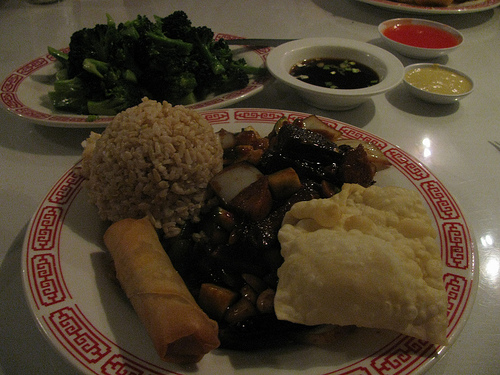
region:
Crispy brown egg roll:
[102, 210, 222, 367]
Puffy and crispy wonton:
[281, 176, 455, 347]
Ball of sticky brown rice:
[82, 97, 218, 230]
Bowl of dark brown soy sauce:
[268, 19, 412, 114]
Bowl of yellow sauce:
[402, 64, 479, 104]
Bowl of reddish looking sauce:
[376, 11, 464, 61]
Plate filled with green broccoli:
[5, 11, 274, 119]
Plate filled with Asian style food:
[28, 108, 473, 370]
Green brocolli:
[47, 24, 247, 88]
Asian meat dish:
[220, 116, 367, 193]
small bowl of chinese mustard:
[403, 58, 475, 110]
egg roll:
[95, 211, 220, 368]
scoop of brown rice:
[76, 101, 227, 233]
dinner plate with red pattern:
[19, 137, 140, 374]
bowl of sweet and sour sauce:
[367, 10, 466, 61]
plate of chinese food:
[20, 104, 475, 374]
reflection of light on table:
[396, 118, 456, 174]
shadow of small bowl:
[390, 73, 467, 120]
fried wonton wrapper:
[272, 164, 454, 354]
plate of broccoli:
[15, 21, 268, 110]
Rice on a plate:
[68, 114, 256, 224]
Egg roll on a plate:
[86, 223, 226, 352]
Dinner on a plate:
[89, 121, 471, 367]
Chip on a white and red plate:
[277, 195, 484, 345]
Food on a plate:
[135, 166, 300, 337]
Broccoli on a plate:
[51, 20, 274, 120]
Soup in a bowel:
[280, 37, 372, 117]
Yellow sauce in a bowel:
[405, 67, 460, 89]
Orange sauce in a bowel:
[373, 12, 439, 48]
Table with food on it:
[23, 17, 488, 286]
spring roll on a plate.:
[96, 212, 229, 368]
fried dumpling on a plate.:
[274, 155, 437, 345]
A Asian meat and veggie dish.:
[191, 132, 355, 347]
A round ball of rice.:
[83, 87, 233, 239]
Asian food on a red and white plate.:
[11, 143, 454, 373]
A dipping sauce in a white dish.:
[262, 47, 401, 105]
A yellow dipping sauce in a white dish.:
[416, 57, 476, 116]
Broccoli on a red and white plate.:
[6, 39, 240, 101]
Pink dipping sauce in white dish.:
[355, 13, 475, 52]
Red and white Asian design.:
[36, 297, 113, 369]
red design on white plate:
[23, 251, 75, 301]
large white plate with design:
[2, 166, 214, 372]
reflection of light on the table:
[414, 126, 498, 163]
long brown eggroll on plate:
[79, 216, 208, 358]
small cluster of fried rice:
[102, 103, 224, 209]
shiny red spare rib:
[169, 188, 321, 260]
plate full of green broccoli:
[55, 22, 231, 116]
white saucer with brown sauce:
[231, 31, 421, 116]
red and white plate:
[18, 98, 494, 356]